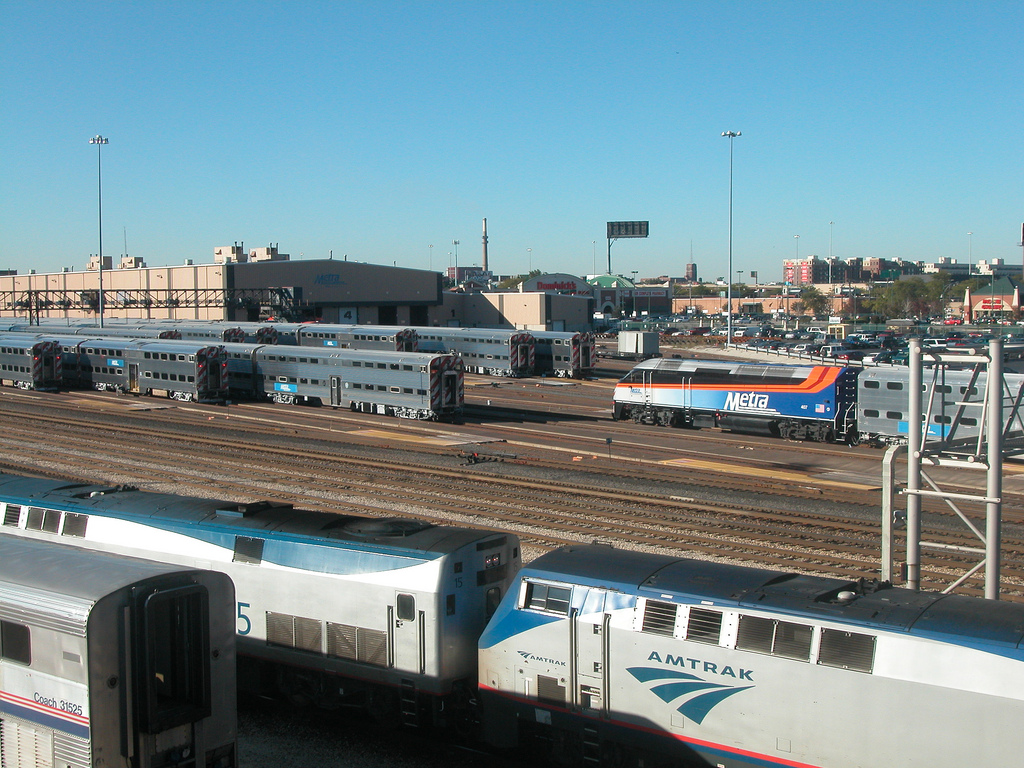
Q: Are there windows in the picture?
A: Yes, there is a window.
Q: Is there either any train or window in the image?
A: Yes, there is a window.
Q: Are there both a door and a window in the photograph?
A: Yes, there are both a window and a door.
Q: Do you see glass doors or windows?
A: Yes, there is a glass window.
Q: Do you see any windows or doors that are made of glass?
A: Yes, the window is made of glass.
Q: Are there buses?
A: No, there are no buses.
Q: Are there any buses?
A: No, there are no buses.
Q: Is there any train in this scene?
A: Yes, there is a train.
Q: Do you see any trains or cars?
A: Yes, there is a train.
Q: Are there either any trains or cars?
A: Yes, there is a train.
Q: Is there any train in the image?
A: Yes, there is a train.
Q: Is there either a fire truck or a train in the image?
A: Yes, there is a train.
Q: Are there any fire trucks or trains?
A: Yes, there is a train.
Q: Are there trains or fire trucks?
A: Yes, there is a train.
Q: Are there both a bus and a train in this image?
A: No, there is a train but no buses.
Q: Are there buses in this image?
A: No, there are no buses.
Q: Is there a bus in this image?
A: No, there are no buses.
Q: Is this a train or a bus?
A: This is a train.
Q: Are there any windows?
A: Yes, there is a window.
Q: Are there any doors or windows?
A: Yes, there is a window.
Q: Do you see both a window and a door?
A: Yes, there are both a window and a door.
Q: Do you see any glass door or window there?
A: Yes, there is a glass window.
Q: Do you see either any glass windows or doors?
A: Yes, there is a glass window.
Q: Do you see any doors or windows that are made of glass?
A: Yes, the window is made of glass.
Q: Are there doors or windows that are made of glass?
A: Yes, the window is made of glass.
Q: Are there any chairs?
A: No, there are no chairs.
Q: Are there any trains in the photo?
A: Yes, there is a train.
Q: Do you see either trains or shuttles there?
A: Yes, there is a train.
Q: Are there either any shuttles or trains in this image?
A: Yes, there is a train.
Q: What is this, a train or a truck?
A: This is a train.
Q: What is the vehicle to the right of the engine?
A: The vehicle is a train.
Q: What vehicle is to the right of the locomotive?
A: The vehicle is a train.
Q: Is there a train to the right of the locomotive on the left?
A: Yes, there is a train to the right of the locomotive.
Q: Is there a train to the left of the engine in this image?
A: No, the train is to the right of the engine.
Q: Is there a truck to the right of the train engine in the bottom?
A: No, there is a train to the right of the train engine.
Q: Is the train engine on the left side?
A: Yes, the train engine is on the left of the image.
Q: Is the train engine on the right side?
A: No, the train engine is on the left of the image.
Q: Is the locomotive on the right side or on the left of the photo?
A: The locomotive is on the left of the image.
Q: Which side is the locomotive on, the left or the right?
A: The locomotive is on the left of the image.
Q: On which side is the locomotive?
A: The locomotive is on the left of the image.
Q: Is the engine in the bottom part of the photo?
A: Yes, the engine is in the bottom of the image.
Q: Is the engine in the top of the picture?
A: No, the engine is in the bottom of the image.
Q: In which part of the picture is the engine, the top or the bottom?
A: The engine is in the bottom of the image.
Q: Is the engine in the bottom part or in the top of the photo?
A: The engine is in the bottom of the image.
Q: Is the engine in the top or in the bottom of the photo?
A: The engine is in the bottom of the image.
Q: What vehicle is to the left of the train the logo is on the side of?
A: The vehicle is a locomotive.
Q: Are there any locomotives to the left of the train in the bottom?
A: Yes, there is a locomotive to the left of the train.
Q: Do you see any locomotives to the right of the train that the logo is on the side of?
A: No, the locomotive is to the left of the train.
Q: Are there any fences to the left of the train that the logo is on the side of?
A: No, there is a locomotive to the left of the train.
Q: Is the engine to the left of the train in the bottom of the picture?
A: Yes, the engine is to the left of the train.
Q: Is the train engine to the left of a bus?
A: No, the train engine is to the left of the train.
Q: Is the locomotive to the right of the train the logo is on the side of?
A: No, the locomotive is to the left of the train.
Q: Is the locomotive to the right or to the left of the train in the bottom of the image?
A: The locomotive is to the left of the train.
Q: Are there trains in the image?
A: Yes, there is a train.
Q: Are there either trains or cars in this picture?
A: Yes, there is a train.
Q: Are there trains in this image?
A: Yes, there is a train.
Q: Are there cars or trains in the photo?
A: Yes, there is a train.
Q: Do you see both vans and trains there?
A: No, there is a train but no vans.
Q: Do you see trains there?
A: Yes, there is a train.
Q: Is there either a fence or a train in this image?
A: Yes, there is a train.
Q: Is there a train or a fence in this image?
A: Yes, there is a train.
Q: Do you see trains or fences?
A: Yes, there is a train.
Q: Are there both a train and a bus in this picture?
A: No, there is a train but no buses.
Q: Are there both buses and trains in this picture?
A: No, there is a train but no buses.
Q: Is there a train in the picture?
A: Yes, there is a train.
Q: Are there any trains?
A: Yes, there is a train.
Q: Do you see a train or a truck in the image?
A: Yes, there is a train.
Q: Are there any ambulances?
A: No, there are no ambulances.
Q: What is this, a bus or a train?
A: This is a train.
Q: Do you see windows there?
A: Yes, there is a window.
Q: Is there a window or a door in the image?
A: Yes, there is a window.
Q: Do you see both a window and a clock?
A: No, there is a window but no clocks.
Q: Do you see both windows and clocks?
A: No, there is a window but no clocks.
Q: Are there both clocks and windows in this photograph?
A: No, there is a window but no clocks.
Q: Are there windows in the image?
A: Yes, there is a window.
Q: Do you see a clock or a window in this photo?
A: Yes, there is a window.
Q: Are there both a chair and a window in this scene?
A: No, there is a window but no chairs.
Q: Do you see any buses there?
A: No, there are no buses.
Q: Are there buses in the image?
A: No, there are no buses.